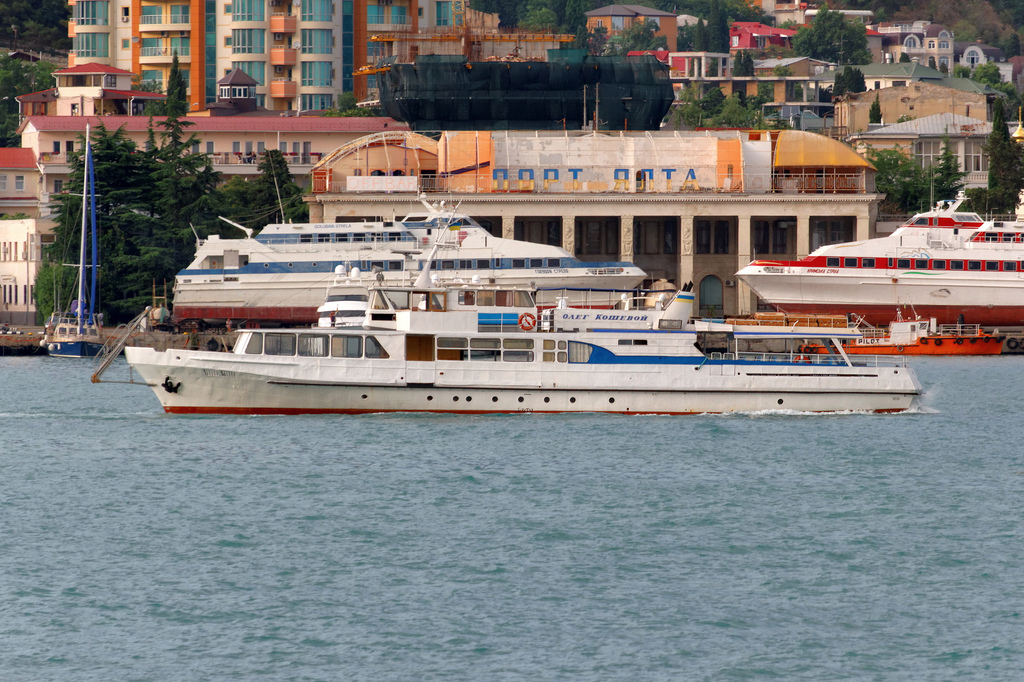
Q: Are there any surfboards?
A: No, there are no surfboards.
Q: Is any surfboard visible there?
A: No, there are no surfboards.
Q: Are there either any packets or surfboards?
A: No, there are no surfboards or packets.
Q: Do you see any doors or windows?
A: Yes, there is a window.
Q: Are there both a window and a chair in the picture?
A: No, there is a window but no chairs.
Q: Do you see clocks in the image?
A: No, there are no clocks.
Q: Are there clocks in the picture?
A: No, there are no clocks.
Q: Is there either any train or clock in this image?
A: No, there are no clocks or trains.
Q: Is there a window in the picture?
A: Yes, there is a window.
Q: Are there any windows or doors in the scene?
A: Yes, there is a window.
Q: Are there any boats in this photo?
A: Yes, there is a boat.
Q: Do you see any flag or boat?
A: Yes, there is a boat.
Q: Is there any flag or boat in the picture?
A: Yes, there is a boat.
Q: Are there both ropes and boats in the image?
A: No, there is a boat but no ropes.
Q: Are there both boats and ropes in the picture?
A: No, there is a boat but no ropes.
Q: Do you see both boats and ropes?
A: No, there is a boat but no ropes.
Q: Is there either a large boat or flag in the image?
A: Yes, there is a large boat.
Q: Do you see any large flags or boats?
A: Yes, there is a large boat.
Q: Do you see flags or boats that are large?
A: Yes, the boat is large.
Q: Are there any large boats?
A: Yes, there is a large boat.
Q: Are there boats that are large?
A: Yes, there is a boat that is large.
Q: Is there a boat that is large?
A: Yes, there is a boat that is large.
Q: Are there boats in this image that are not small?
A: Yes, there is a large boat.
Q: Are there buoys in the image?
A: No, there are no buoys.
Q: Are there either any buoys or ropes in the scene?
A: No, there are no buoys or ropes.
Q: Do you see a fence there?
A: No, there are no fences.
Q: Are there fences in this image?
A: No, there are no fences.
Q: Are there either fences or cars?
A: No, there are no fences or cars.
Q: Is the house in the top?
A: Yes, the house is in the top of the image.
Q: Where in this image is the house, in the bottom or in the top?
A: The house is in the top of the image.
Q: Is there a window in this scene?
A: Yes, there is a window.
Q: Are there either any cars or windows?
A: Yes, there is a window.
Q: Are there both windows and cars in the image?
A: No, there is a window but no cars.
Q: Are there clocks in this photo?
A: No, there are no clocks.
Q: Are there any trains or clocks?
A: No, there are no clocks or trains.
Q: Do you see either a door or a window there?
A: Yes, there is a window.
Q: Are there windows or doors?
A: Yes, there is a window.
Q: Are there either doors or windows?
A: Yes, there is a window.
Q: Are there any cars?
A: No, there are no cars.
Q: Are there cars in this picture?
A: No, there are no cars.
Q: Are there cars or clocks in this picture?
A: No, there are no cars or clocks.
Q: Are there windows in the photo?
A: Yes, there is a window.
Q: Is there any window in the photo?
A: Yes, there is a window.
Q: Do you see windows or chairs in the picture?
A: Yes, there is a window.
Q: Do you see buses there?
A: No, there are no buses.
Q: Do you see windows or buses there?
A: Yes, there is a window.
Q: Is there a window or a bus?
A: Yes, there is a window.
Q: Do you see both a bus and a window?
A: No, there is a window but no buses.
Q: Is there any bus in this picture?
A: No, there are no buses.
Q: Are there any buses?
A: No, there are no buses.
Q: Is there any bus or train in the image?
A: No, there are no buses or trains.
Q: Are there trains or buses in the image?
A: No, there are no buses or trains.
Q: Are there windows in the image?
A: Yes, there is a window.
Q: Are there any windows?
A: Yes, there is a window.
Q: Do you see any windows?
A: Yes, there is a window.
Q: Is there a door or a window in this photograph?
A: Yes, there is a window.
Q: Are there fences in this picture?
A: No, there are no fences.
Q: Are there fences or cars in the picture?
A: No, there are no fences or cars.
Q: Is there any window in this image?
A: Yes, there is a window.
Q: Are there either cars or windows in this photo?
A: Yes, there is a window.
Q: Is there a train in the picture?
A: No, there are no trains.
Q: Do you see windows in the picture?
A: Yes, there is a window.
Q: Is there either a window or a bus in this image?
A: Yes, there is a window.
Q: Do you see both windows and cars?
A: No, there is a window but no cars.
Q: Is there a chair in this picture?
A: No, there are no chairs.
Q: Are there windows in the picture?
A: Yes, there is a window.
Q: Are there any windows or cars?
A: Yes, there is a window.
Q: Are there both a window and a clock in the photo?
A: No, there is a window but no clocks.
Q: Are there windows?
A: Yes, there is a window.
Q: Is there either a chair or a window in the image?
A: Yes, there is a window.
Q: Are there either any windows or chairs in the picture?
A: Yes, there is a window.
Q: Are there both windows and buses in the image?
A: No, there is a window but no buses.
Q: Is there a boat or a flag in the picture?
A: Yes, there is a boat.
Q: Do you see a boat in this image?
A: Yes, there is a boat.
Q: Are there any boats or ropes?
A: Yes, there is a boat.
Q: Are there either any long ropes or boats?
A: Yes, there is a long boat.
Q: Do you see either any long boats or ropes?
A: Yes, there is a long boat.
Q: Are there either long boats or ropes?
A: Yes, there is a long boat.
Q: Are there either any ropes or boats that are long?
A: Yes, the boat is long.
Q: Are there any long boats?
A: Yes, there is a long boat.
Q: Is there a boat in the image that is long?
A: Yes, there is a boat that is long.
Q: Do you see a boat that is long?
A: Yes, there is a boat that is long.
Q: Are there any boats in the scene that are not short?
A: Yes, there is a long boat.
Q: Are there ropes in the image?
A: No, there are no ropes.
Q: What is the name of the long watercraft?
A: The watercraft is a boat.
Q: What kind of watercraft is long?
A: The watercraft is a boat.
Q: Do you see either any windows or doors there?
A: Yes, there is a window.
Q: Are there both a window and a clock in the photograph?
A: No, there is a window but no clocks.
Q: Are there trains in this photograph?
A: No, there are no trains.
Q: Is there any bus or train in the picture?
A: No, there are no trains or buses.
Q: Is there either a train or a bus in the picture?
A: No, there are no trains or buses.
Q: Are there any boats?
A: Yes, there is a boat.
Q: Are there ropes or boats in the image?
A: Yes, there is a boat.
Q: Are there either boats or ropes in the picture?
A: Yes, there is a boat.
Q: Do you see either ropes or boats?
A: Yes, there is a boat.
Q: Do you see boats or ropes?
A: Yes, there is a boat.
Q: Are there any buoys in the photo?
A: No, there are no buoys.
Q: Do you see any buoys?
A: No, there are no buoys.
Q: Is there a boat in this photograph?
A: Yes, there is a boat.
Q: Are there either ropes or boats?
A: Yes, there is a boat.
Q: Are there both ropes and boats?
A: No, there is a boat but no ropes.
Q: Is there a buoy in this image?
A: No, there are no buoys.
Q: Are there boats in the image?
A: Yes, there is a boat.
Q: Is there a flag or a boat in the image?
A: Yes, there is a boat.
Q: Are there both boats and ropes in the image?
A: No, there is a boat but no ropes.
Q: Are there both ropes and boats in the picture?
A: No, there is a boat but no ropes.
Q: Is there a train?
A: No, there are no trains.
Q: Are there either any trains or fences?
A: No, there are no trains or fences.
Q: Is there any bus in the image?
A: No, there are no buses.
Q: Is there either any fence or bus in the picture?
A: No, there are no buses or fences.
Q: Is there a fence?
A: No, there are no fences.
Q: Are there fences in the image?
A: No, there are no fences.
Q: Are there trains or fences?
A: No, there are no fences or trains.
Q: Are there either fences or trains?
A: No, there are no fences or trains.